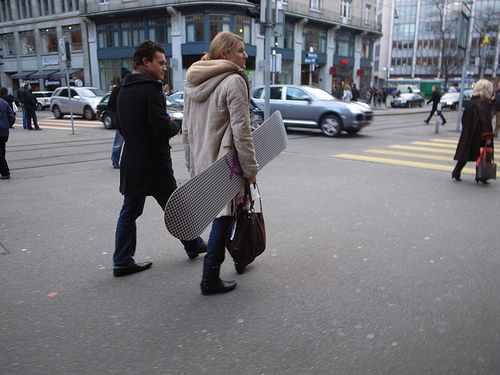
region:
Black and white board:
[157, 91, 301, 248]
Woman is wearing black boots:
[193, 237, 268, 319]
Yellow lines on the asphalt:
[347, 117, 491, 207]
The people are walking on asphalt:
[88, 27, 299, 336]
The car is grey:
[263, 76, 401, 161]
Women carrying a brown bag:
[429, 78, 495, 198]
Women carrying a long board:
[178, 28, 296, 271]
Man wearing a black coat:
[103, 36, 218, 281]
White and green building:
[42, 5, 378, 117]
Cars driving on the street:
[44, 61, 363, 153]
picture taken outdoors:
[50, 33, 475, 305]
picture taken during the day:
[38, 38, 497, 330]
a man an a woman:
[107, 89, 308, 301]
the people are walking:
[78, 52, 352, 330]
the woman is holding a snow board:
[144, 108, 302, 280]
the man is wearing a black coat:
[96, 51, 196, 232]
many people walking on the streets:
[20, 83, 465, 220]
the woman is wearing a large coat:
[188, 89, 271, 223]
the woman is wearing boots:
[184, 228, 265, 341]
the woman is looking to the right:
[196, 33, 323, 131]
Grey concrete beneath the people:
[293, 262, 413, 344]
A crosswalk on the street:
[370, 128, 481, 184]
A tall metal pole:
[57, 34, 99, 140]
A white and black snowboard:
[165, 116, 327, 242]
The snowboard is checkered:
[142, 120, 315, 225]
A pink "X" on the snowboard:
[220, 151, 247, 184]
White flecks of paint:
[360, 322, 410, 355]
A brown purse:
[470, 154, 498, 185]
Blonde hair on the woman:
[202, 30, 244, 60]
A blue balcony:
[87, 39, 138, 57]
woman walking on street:
[169, 25, 291, 295]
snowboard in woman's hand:
[160, 108, 292, 244]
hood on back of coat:
[172, 49, 239, 108]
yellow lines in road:
[340, 134, 446, 174]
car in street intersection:
[255, 80, 380, 140]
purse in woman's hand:
[225, 175, 270, 269]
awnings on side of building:
[14, 65, 84, 83]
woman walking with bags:
[444, 71, 498, 188]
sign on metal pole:
[49, 32, 79, 110]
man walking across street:
[416, 79, 453, 136]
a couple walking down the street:
[101, 39, 281, 296]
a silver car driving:
[254, 75, 386, 140]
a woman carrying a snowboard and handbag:
[181, 29, 284, 306]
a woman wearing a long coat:
[454, 67, 499, 202]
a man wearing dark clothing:
[113, 27, 183, 284]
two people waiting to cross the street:
[12, 72, 48, 131]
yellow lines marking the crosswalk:
[390, 120, 459, 167]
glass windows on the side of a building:
[88, 21, 178, 53]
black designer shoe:
[102, 249, 156, 280]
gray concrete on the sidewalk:
[276, 181, 497, 363]